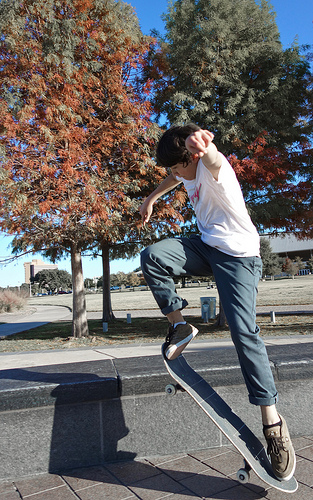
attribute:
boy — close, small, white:
[127, 111, 292, 417]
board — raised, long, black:
[154, 346, 299, 495]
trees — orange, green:
[1, 2, 312, 260]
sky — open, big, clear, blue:
[0, 2, 312, 81]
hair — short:
[150, 124, 204, 172]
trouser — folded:
[143, 227, 286, 415]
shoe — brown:
[162, 324, 198, 355]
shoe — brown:
[259, 414, 293, 481]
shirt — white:
[156, 153, 256, 263]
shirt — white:
[159, 139, 261, 262]